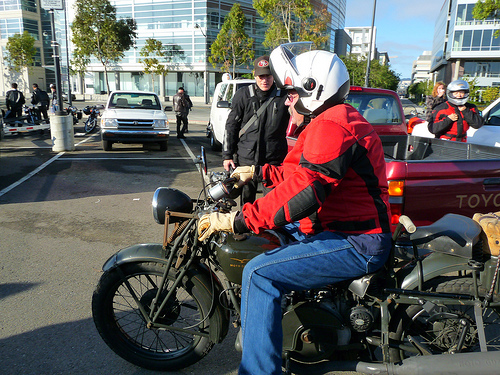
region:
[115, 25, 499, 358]
Man on a motorcycle being watched by another man.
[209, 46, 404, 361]
Man on a motorcycle.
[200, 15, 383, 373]
Man in a red jacket and blue jeans on a motorcycle.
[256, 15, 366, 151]
White helmet being worn by a man on a motorcycle.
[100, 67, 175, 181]
A white pickup truck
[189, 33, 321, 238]
a man in a black jacket watching the man on the motorcycle.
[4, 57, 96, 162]
A group of men next to motorcycles.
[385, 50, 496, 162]
Man in a black and red jacket.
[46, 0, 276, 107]
Building with many windows.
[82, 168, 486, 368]
A black motorcycle.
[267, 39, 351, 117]
A white helmet on a man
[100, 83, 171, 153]
A white car on the road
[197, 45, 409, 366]
A guy riding a motorcycle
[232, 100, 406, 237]
A red jacket on a man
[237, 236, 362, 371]
A pair of blue jeans on a man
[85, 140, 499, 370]
A motorcycle on the street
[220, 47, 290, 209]
A man with black jacket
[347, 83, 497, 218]
A red Toyota pickup on the street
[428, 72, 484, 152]
A person with a helmet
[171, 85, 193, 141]
A person walking on the street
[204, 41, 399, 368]
man on a motorcycle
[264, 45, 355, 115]
man's white colored riding helmet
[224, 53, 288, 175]
man with a black baseball cap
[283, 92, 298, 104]
man's red colored sunglasses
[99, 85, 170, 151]
front end of a white vehicle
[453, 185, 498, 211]
part of the word Toyota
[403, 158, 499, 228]
tailgate of a red pickup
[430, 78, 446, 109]
a redheaded woman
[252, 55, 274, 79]
black baseball cap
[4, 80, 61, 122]
group of bikers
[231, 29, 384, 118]
White and black motor cycle helmet.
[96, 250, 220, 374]
Black tires with black spokes.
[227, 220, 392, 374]
A pair of blue jeans.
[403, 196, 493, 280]
A black seat of motor cycle.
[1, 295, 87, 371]
Shadow on the ground.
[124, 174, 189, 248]
Black and silver light on motorcycle.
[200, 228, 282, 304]
Green and yellow middle of cycle.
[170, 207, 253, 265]
A glove on a hand.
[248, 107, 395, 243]
Red and black motorcycle jacket.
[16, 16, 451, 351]
A group of people in a parking lot.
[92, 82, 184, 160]
car is white and parked